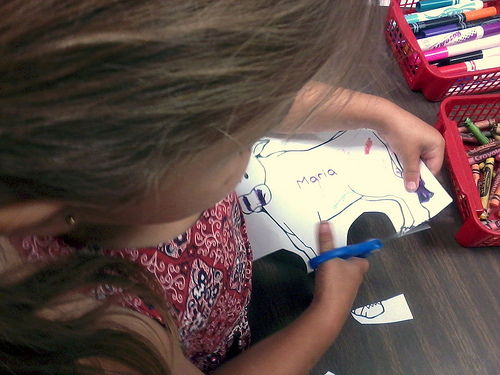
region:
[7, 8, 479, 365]
A LITTLE GIRL CUTTING PAAER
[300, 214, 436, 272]
A BLUE PAIR OF SCISSORS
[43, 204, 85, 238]
AN EARING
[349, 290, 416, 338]
A PIECE OF CUT PAPER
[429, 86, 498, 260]
A BIN OF CRYONS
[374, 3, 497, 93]
A BIN OF COLORED MARKERS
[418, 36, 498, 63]
A PINK MARKER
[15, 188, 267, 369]
A CHILD'S TOP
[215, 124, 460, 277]
SCISSORS CUTTING PAPER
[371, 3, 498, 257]
TWO RED BINS ON A TABLE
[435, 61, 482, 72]
Red marker in a basket.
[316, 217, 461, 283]
Blue scissors in the girls hand.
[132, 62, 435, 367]
Little girl cutting paper.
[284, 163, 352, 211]
Paper with Maria written on it.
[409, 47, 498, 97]
Red basket with markers and crayons.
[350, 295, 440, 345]
Piece of paper the girl cut off.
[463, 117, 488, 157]
Green crayon in the basket.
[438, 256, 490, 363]
Wooden table the girl is sitting at.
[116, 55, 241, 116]
The little girl's brown hair.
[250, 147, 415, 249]
A drawing of a cow.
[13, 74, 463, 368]
Picture is taken indoors.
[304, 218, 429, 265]
Girl is holding a blue pair of scissors.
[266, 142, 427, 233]
The name Maria is on the picture of a cow.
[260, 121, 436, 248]
The girls is cutting out the picture of a cow.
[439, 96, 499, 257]
A box of crayons.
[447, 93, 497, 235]
There are many colors of crayons.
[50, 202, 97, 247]
The girl has an earring.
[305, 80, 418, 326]
The girl is using her right hand with the scissors.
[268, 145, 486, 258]
The cow is black and white.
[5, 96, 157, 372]
The girl has long hair.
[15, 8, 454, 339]
The girl is holding scissors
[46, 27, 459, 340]
The girl is cutting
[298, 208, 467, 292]
The scissors are blue and silver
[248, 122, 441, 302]
This is a picture of a cow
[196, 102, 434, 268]
The cow's name is Maria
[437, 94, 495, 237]
Crayons are in this basket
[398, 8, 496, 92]
Markers are in this basket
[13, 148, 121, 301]
The girl is wearing an earring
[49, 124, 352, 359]
The shirt is patterned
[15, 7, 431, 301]
The girl has brown hair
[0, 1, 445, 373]
Little girl with brown hair cutting out a picture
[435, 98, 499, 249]
A red basket of crayons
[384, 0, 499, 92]
A red basket of markers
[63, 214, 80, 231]
An earring on her ear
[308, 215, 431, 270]
Blue scissors cutting edge of paper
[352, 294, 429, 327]
A small piece of paper lying on the table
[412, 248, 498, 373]
A brown table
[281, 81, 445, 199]
Little girl's arm and hand holding the paper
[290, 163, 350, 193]
The name Maria in the middle of the drawing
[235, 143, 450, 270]
Drawing of a cow